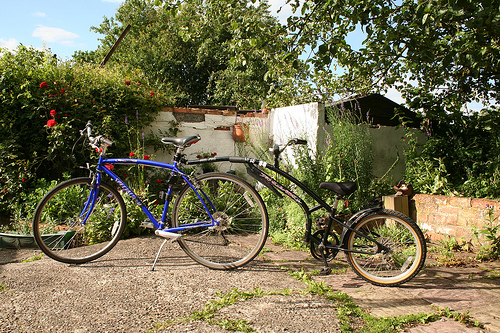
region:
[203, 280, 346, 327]
Grass growing from the cracks.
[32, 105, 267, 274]
A parked bright blue bike.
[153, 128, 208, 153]
Blue bike with a black seat.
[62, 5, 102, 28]
Patch of blue sky in the background.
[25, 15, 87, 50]
Blue sky with puffy white clouds.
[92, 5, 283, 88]
Big tree with green leaves.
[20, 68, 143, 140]
Roses climbing over the wall.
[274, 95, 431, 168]
White shed under the trees.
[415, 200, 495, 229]
Small wall made of bricks.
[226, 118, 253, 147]
Small terra cotta pot on the wall.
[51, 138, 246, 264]
bike is blue in color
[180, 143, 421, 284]
bike is black in color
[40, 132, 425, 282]
bike is tethered together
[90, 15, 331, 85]
trees in the behind the wall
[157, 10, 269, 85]
trees are green in color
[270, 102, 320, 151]
wall is white in color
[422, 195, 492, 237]
brick wall near bikes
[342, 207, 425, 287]
black bike has small wheel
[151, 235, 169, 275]
bike has kick stand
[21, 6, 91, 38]
sky is blue in color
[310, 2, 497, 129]
green leaves on tree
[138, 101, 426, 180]
white wall of building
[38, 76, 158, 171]
red flowers on bush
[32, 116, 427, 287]
sides of two parked bikes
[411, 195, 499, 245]
red stones of wall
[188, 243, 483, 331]
weeds in cement cracks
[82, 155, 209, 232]
blue body of bike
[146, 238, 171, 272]
kickstand on top of cement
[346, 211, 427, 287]
back tire of bike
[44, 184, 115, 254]
spokes in bike tire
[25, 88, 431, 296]
two bikes in front a house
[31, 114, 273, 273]
a bike color blue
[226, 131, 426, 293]
a bike color black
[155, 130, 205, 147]
sit of bike is black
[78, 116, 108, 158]
handles of bike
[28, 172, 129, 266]
front wheel of bike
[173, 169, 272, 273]
back wheel of bike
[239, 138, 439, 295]
black bike is missing a wheel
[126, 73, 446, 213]
a small white house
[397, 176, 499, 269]
a small wall of brick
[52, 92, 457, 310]
a bicycle with seat extension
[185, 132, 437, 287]
a bicycle extension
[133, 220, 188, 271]
kick stand on the bike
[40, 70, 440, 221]
white building behind the bike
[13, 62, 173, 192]
red flowers on the bushes on the left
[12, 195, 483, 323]
cement ground with grass growing in the cracks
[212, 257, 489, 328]
grass growing in the cement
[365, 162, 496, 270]
brick wall on the right behind the bike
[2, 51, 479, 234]
trees and foilage surrounding the building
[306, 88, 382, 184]
bushes with purple flowers on the top